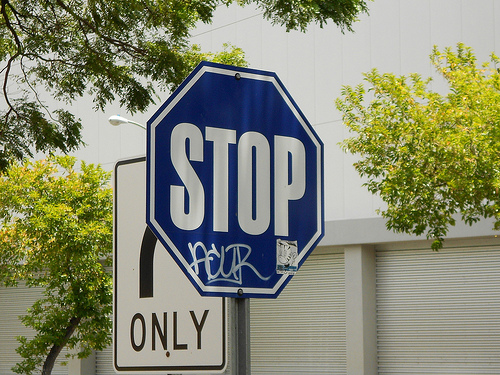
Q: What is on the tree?
A: Leaves.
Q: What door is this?
A: Garage.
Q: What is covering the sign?
A: Traffic sign.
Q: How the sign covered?
A: Partial.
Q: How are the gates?
A: Metal.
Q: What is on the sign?
A: White graffiti.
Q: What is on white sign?
A: Black curve.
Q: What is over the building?
A: Light colored leaves on branches.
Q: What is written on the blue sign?
A: STOP.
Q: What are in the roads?
A: Signs.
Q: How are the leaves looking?
A: Green.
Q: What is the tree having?
A: Branches.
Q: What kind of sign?
A: Stop.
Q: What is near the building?
A: Tree.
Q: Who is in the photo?
A: Nobody.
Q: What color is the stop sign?
A: Blue.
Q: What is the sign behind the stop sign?
A: Right only.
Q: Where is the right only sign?
A: Behind the stop sign.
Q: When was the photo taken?
A: Daytime.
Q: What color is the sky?
A: Grey.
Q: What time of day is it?
A: Morning.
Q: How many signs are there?
A: Two.